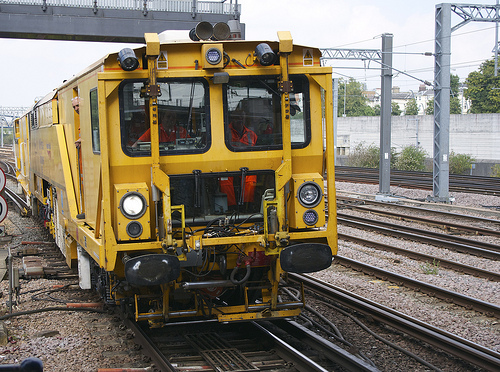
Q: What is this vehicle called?
A: Train.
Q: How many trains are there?
A: One.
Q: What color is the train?
A: Yellow.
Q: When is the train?
A: On a track.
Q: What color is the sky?
A: Blue.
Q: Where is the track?
A: Under the train.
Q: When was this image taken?
A: Daytime.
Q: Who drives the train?
A: Engineer.